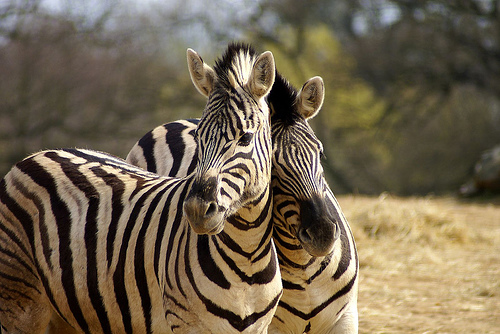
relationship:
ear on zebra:
[183, 46, 219, 98] [2, 41, 284, 332]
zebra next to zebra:
[2, 41, 284, 332] [126, 67, 360, 334]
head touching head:
[185, 46, 277, 237] [266, 74, 340, 256]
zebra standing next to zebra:
[2, 41, 284, 332] [126, 67, 360, 334]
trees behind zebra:
[1, 5, 498, 210] [2, 41, 284, 332]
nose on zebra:
[187, 197, 219, 220] [2, 41, 284, 332]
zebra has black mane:
[126, 67, 360, 334] [266, 71, 315, 132]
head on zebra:
[185, 46, 281, 237] [2, 41, 284, 332]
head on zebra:
[266, 69, 343, 259] [126, 67, 360, 334]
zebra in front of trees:
[126, 67, 360, 334] [1, 5, 498, 210]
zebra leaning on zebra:
[126, 67, 360, 334] [2, 41, 284, 332]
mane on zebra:
[210, 38, 259, 108] [2, 41, 284, 332]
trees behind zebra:
[1, 5, 498, 210] [126, 67, 360, 334]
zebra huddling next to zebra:
[126, 67, 360, 334] [2, 41, 284, 332]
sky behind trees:
[9, 1, 499, 67] [1, 5, 498, 210]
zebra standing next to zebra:
[126, 67, 360, 334] [2, 41, 284, 332]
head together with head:
[185, 46, 277, 237] [266, 74, 340, 256]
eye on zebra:
[238, 132, 254, 146] [2, 41, 284, 332]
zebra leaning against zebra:
[126, 67, 360, 334] [2, 41, 284, 332]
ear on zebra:
[248, 48, 277, 101] [2, 41, 284, 332]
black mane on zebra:
[270, 67, 299, 126] [126, 67, 360, 334]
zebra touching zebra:
[126, 67, 360, 334] [2, 41, 284, 332]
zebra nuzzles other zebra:
[126, 67, 360, 334] [2, 41, 284, 332]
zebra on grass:
[2, 41, 284, 332] [334, 197, 499, 330]